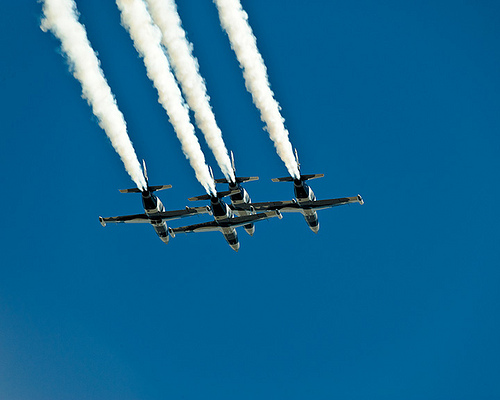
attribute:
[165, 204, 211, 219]
wing — long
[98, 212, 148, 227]
wing — long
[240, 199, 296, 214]
wing — long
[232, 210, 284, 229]
wing — long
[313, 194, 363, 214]
wing — long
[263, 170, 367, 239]
plane — white, green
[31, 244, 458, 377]
sky — blue, clear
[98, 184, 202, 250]
plane — white, black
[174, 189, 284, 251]
plane — white, black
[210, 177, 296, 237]
plane — white, black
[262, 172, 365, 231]
plane — white, black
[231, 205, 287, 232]
wing — long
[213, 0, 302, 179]
contrail — white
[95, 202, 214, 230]
wings — narrow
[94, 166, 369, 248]
planes — four